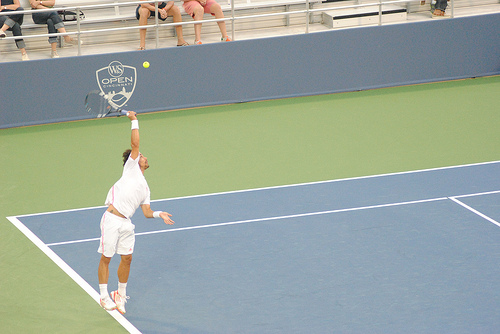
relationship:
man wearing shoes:
[96, 110, 174, 320] [99, 279, 134, 316]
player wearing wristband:
[39, 89, 227, 323] [119, 101, 159, 145]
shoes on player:
[91, 289, 236, 301] [39, 89, 227, 323]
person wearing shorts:
[182, 0, 229, 46] [184, 1, 234, 33]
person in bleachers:
[182, 0, 229, 46] [52, 4, 243, 46]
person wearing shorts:
[97, 110, 170, 312] [96, 212, 137, 258]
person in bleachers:
[97, 110, 170, 312] [52, 4, 243, 46]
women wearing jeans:
[4, 4, 76, 60] [0, 5, 65, 51]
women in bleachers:
[4, 4, 76, 60] [5, 0, 497, 60]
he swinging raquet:
[87, 115, 171, 310] [80, 87, 126, 117]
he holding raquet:
[94, 107, 177, 317] [80, 87, 126, 117]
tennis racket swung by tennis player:
[77, 86, 134, 128] [94, 110, 175, 319]